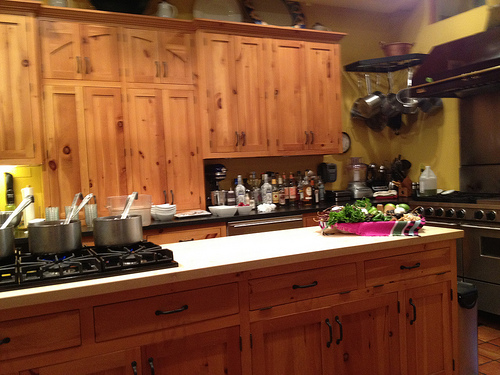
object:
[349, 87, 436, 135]
pots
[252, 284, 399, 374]
kitchen cabinets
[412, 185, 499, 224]
stove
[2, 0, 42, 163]
cabinets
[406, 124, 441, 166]
ground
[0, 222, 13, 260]
burner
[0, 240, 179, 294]
burner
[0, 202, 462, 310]
table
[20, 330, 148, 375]
cabinets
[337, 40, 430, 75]
rack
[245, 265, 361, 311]
cabinet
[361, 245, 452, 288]
cabinet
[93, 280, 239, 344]
cabinet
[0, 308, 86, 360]
cabinet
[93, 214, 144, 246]
pot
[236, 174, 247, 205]
bottle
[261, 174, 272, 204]
bottle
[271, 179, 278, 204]
bottle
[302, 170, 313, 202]
bottle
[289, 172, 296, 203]
bottle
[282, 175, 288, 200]
bottle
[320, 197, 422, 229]
vegetables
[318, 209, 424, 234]
basket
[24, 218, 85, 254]
pot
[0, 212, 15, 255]
pot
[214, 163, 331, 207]
floral bag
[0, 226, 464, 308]
counter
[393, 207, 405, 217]
vegetable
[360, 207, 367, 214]
vegetable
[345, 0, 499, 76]
ceiling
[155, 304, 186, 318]
handle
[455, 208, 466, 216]
knob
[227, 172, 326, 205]
condiments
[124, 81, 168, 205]
cabinet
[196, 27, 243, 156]
cabinet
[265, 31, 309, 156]
cabinet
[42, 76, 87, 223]
cabinet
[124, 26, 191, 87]
cabinet